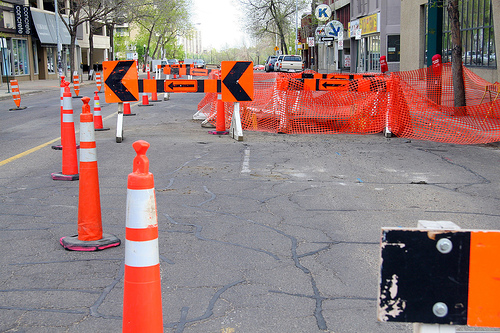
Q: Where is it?
A: This is at the road.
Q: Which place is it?
A: It is a road.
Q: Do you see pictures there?
A: No, there are no pictures.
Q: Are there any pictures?
A: No, there are no pictures.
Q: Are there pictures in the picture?
A: No, there are no pictures.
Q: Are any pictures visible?
A: No, there are no pictures.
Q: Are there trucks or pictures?
A: No, there are no pictures or trucks.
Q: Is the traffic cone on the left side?
A: Yes, the traffic cone is on the left of the image.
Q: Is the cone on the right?
A: No, the cone is on the left of the image.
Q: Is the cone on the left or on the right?
A: The cone is on the left of the image.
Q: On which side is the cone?
A: The cone is on the left of the image.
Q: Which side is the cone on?
A: The cone is on the left of the image.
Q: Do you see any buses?
A: No, there are no buses.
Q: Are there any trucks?
A: No, there are no trucks.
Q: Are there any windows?
A: Yes, there are windows.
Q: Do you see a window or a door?
A: Yes, there are windows.